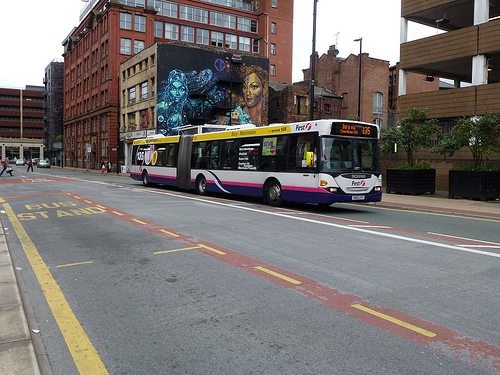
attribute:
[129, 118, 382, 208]
bus — long, blue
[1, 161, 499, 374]
highway — asphalt, grey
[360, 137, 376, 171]
door — closed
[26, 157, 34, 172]
person — walking, crossing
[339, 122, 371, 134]
words — orange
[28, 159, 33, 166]
blouse — red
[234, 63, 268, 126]
woman — painted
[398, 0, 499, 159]
parking ramp — brown, here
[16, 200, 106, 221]
words — yellow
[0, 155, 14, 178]
person — walking, crossing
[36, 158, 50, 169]
car — driving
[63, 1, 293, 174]
building — red, tall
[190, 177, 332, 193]
stripe — pink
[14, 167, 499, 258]
line — white, painted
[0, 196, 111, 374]
line — yellow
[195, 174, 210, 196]
wheel — black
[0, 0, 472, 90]
sky — white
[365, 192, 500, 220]
sidewalk — concrete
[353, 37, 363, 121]
street light — tall